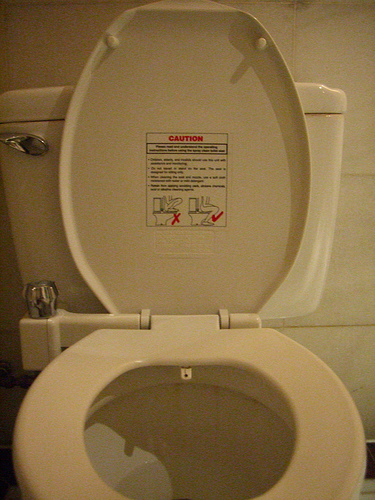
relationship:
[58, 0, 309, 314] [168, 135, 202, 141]
lid has writing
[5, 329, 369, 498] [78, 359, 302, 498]
toilet bowl has shadow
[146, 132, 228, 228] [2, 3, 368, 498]
sign on toilet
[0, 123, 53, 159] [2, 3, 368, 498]
flush knob on toilet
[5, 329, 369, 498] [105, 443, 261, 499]
toilet bowl has water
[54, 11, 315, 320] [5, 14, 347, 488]
lid on toilet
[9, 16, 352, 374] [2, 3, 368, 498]
wall behind toilet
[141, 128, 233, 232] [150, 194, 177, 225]
sign says people cannot stand on toilet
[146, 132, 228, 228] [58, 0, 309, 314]
sign on lid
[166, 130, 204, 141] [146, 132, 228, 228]
writing on sign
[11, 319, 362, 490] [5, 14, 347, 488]
seat of toilet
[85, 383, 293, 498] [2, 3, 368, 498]
shadow in toilet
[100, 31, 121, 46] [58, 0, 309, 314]
peg on lid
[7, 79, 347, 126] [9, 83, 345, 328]
lid of top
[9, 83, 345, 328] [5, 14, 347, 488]
top of toilet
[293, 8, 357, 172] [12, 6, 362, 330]
tile on wall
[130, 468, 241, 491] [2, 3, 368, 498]
water in toilet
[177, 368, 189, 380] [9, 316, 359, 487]
metal sticking out on toilet seat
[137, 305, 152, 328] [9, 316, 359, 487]
hinge on toilet seat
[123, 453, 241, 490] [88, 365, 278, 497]
water at bottom of toilet bowl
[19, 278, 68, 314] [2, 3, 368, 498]
knob on back right of toilet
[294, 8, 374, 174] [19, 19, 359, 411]
tile on wall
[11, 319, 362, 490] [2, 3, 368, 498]
seat of a toilet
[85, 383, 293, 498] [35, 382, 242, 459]
shadow on toilet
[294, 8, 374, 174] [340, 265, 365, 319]
tile on wall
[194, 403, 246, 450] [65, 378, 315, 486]
shadow on toilet